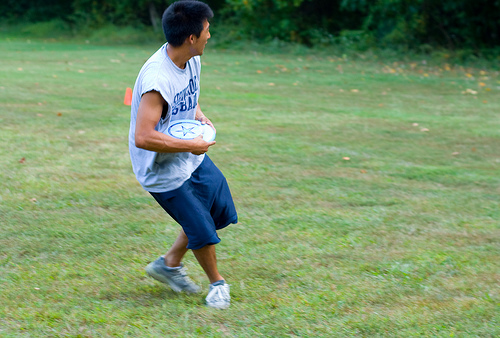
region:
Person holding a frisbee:
[123, 0, 242, 322]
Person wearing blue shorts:
[125, 0, 257, 326]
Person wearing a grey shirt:
[105, 0, 278, 322]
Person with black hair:
[109, 0, 276, 330]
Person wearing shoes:
[89, 0, 291, 333]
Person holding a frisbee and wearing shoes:
[82, 0, 280, 323]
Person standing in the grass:
[75, 0, 295, 330]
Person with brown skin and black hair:
[86, 0, 298, 330]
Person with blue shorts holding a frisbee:
[65, 0, 295, 327]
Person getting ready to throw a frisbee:
[90, 0, 292, 332]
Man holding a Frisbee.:
[128, 0, 239, 305]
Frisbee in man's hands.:
[166, 118, 216, 143]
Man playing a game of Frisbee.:
[127, 2, 237, 308]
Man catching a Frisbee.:
[127, 0, 239, 307]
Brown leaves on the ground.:
[256, 48, 493, 113]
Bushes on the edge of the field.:
[233, 2, 497, 54]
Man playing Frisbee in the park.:
[9, 2, 490, 335]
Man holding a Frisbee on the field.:
[5, 3, 496, 325]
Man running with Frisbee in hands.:
[45, 4, 430, 332]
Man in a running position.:
[120, 0, 262, 335]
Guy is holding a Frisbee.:
[166, 112, 220, 158]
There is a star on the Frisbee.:
[175, 120, 200, 145]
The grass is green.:
[341, 212, 417, 276]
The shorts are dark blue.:
[153, 187, 233, 217]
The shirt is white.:
[131, 67, 203, 137]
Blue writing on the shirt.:
[165, 74, 211, 122]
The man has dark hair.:
[140, 0, 223, 42]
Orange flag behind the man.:
[109, 65, 148, 135]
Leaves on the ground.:
[377, 57, 499, 122]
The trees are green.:
[255, 6, 430, 45]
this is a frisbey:
[170, 120, 215, 150]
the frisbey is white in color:
[175, 120, 212, 142]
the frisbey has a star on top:
[177, 121, 193, 132]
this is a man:
[138, 5, 238, 310]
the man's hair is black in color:
[171, 7, 193, 28]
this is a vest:
[143, 65, 173, 80]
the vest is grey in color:
[147, 65, 168, 81]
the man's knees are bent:
[181, 200, 236, 250]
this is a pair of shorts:
[177, 192, 217, 212]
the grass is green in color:
[26, 111, 103, 274]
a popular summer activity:
[49, 0, 475, 302]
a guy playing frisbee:
[105, 1, 298, 318]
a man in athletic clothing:
[116, 1, 259, 316]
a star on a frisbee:
[151, 112, 229, 159]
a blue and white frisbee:
[148, 113, 223, 160]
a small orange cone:
[116, 86, 140, 110]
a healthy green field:
[31, 24, 488, 319]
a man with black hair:
[144, 0, 231, 74]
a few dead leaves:
[321, 44, 471, 115]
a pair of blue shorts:
[137, 148, 264, 255]